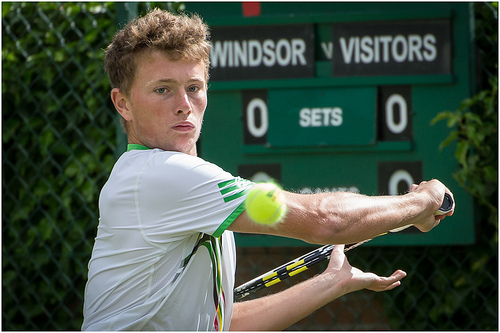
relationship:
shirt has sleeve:
[113, 132, 218, 332] [162, 158, 254, 227]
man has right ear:
[105, 28, 227, 333] [112, 92, 139, 125]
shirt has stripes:
[113, 132, 218, 332] [195, 237, 240, 284]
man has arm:
[105, 28, 227, 333] [307, 181, 405, 236]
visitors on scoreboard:
[346, 23, 436, 89] [231, 4, 484, 179]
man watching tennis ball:
[105, 28, 227, 333] [245, 183, 291, 223]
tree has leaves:
[439, 94, 494, 192] [424, 102, 476, 146]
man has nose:
[105, 28, 227, 333] [171, 91, 196, 120]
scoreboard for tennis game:
[231, 4, 484, 179] [72, 6, 468, 331]